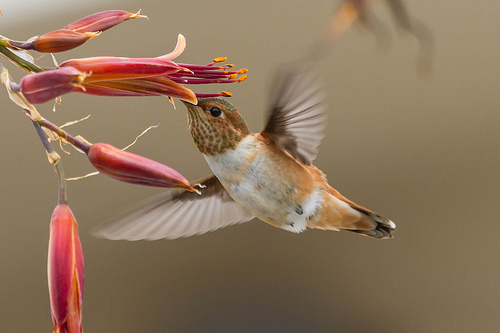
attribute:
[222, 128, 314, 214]
bird's fur — brown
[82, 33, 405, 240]
bird — small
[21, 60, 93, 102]
flower petals — red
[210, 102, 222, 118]
eye — of a humming bird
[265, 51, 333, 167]
flapping wing — of a humming bird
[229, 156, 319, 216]
brown/white feathers — of a humming bird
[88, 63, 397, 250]
humming bird — searching in a flower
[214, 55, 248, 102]
yellow pollen — of flower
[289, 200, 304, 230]
feet — of a humming bird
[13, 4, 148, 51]
pink flowers — ready to bloom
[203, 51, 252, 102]
flower top — yellow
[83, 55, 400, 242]
bird — drinking nectar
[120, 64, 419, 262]
hummingbird — hovering, in the air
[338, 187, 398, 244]
feathers — tail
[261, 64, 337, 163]
wing — bird, in motion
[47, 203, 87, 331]
flower — closed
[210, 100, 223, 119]
eye — black, hummingbird , with reflection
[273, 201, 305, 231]
feet — tucked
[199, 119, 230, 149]
chin — bird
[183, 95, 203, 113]
beak — bird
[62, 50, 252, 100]
flower — nectar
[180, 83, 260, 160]
head — bird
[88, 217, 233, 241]
tips — white